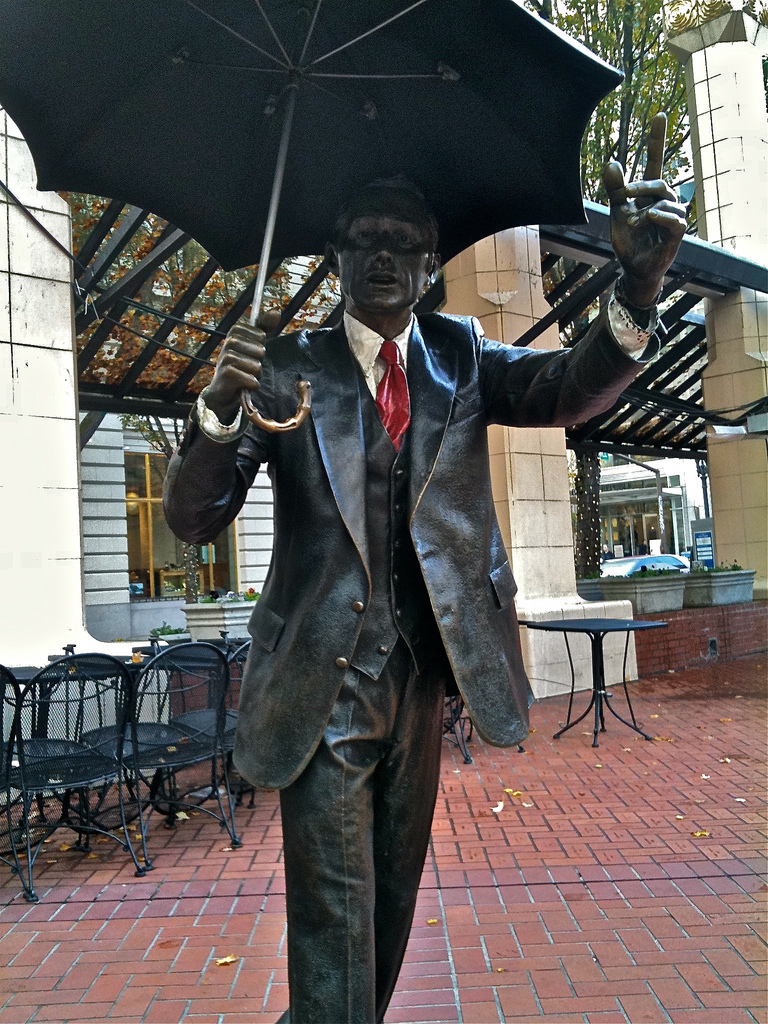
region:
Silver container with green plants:
[684, 555, 762, 604]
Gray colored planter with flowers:
[173, 585, 265, 642]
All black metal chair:
[80, 639, 248, 870]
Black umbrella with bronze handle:
[9, 6, 626, 430]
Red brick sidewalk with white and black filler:
[12, 644, 763, 1020]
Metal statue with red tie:
[151, 108, 687, 1015]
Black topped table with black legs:
[527, 592, 670, 757]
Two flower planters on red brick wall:
[573, 555, 766, 669]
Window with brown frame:
[117, 446, 240, 605]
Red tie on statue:
[371, 337, 414, 453]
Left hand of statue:
[594, 105, 689, 318]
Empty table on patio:
[518, 608, 674, 748]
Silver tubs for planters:
[570, 563, 763, 620]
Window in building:
[116, 443, 242, 600]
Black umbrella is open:
[2, 1, 622, 431]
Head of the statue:
[325, 173, 444, 327]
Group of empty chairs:
[2, 634, 310, 900]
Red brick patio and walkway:
[1, 670, 766, 1022]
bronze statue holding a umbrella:
[194, 122, 525, 1009]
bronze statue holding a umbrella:
[34, 75, 710, 1008]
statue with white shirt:
[334, 312, 416, 375]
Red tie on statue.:
[363, 334, 417, 453]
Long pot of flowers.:
[690, 564, 766, 613]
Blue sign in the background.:
[689, 524, 718, 575]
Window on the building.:
[114, 444, 245, 606]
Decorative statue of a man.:
[149, 119, 689, 1021]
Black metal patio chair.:
[12, 649, 152, 911]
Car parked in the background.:
[591, 539, 698, 586]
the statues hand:
[223, 324, 265, 385]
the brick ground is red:
[531, 939, 620, 1000]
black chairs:
[23, 648, 200, 802]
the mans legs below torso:
[252, 644, 458, 1022]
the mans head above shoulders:
[312, 163, 448, 325]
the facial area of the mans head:
[344, 204, 427, 312]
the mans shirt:
[205, 308, 615, 796]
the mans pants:
[267, 659, 451, 1022]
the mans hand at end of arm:
[194, 320, 271, 428]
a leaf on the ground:
[207, 949, 236, 970]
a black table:
[521, 584, 662, 762]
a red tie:
[374, 330, 409, 445]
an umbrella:
[0, 0, 617, 276]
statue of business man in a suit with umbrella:
[5, 5, 695, 1023]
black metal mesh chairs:
[8, 631, 271, 897]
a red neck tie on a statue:
[375, 339, 411, 438]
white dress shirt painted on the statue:
[343, 302, 416, 399]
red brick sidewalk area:
[3, 677, 765, 1022]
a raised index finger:
[600, 107, 691, 313]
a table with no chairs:
[521, 607, 668, 744]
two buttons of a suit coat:
[328, 596, 377, 690]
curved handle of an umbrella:
[236, 0, 314, 438]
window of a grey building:
[126, 445, 234, 597]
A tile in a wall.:
[4, 136, 70, 213]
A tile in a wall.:
[4, 202, 75, 280]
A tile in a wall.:
[8, 272, 76, 349]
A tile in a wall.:
[11, 344, 77, 416]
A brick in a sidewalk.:
[494, 866, 523, 885]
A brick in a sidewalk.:
[184, 877, 216, 896]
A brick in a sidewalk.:
[76, 897, 123, 921]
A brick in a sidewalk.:
[648, 799, 676, 811]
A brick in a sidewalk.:
[33, 881, 82, 905]